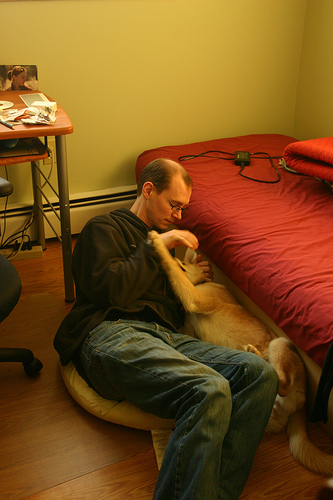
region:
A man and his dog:
[52, 156, 301, 496]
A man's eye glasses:
[159, 195, 190, 212]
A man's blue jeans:
[76, 317, 276, 497]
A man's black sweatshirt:
[53, 208, 183, 368]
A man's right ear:
[140, 181, 158, 201]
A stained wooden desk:
[0, 90, 79, 303]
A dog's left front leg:
[147, 231, 215, 314]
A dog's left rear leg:
[242, 336, 302, 394]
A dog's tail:
[287, 415, 331, 475]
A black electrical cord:
[177, 149, 283, 183]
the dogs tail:
[290, 436, 313, 465]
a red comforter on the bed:
[256, 206, 313, 276]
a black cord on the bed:
[240, 172, 254, 181]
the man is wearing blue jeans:
[109, 336, 157, 373]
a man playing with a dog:
[61, 143, 319, 479]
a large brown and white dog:
[143, 226, 331, 466]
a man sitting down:
[55, 143, 266, 494]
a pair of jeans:
[70, 307, 280, 497]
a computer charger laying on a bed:
[151, 133, 309, 201]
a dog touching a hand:
[138, 222, 332, 438]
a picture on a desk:
[0, 60, 68, 147]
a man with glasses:
[131, 151, 196, 242]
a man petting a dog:
[75, 137, 280, 479]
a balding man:
[119, 151, 232, 261]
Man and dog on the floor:
[63, 158, 307, 473]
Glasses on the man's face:
[147, 185, 196, 219]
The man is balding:
[136, 155, 190, 197]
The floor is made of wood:
[0, 244, 324, 492]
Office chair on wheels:
[0, 168, 48, 378]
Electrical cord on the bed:
[176, 131, 285, 192]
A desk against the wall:
[0, 65, 90, 301]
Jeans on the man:
[84, 304, 285, 492]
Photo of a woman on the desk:
[3, 61, 45, 90]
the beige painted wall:
[72, 1, 290, 124]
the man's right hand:
[149, 228, 200, 250]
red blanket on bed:
[282, 138, 331, 185]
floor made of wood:
[0, 420, 145, 499]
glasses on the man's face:
[158, 188, 190, 213]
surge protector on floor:
[0, 241, 45, 257]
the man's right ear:
[140, 178, 152, 202]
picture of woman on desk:
[3, 62, 36, 92]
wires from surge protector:
[0, 199, 37, 243]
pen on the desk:
[0, 117, 19, 129]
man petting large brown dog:
[70, 152, 298, 445]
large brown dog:
[145, 234, 307, 374]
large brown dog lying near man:
[149, 229, 293, 394]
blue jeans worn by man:
[81, 318, 276, 490]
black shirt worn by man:
[84, 212, 162, 324]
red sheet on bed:
[216, 193, 324, 285]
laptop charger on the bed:
[175, 145, 282, 183]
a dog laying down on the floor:
[147, 230, 332, 475]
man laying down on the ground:
[51, 155, 277, 497]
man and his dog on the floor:
[54, 156, 331, 498]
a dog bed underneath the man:
[59, 352, 177, 467]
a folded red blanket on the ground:
[283, 138, 331, 177]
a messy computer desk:
[0, 89, 74, 302]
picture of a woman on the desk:
[0, 65, 38, 93]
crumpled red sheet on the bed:
[137, 133, 332, 365]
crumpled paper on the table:
[20, 102, 57, 126]